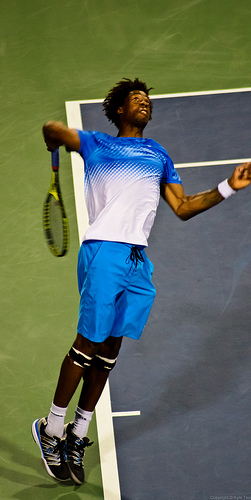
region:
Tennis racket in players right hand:
[38, 117, 67, 254]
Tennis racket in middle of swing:
[41, 123, 64, 249]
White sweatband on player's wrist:
[212, 174, 227, 190]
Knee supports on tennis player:
[62, 341, 109, 362]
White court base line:
[58, 94, 112, 490]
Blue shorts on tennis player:
[69, 236, 148, 327]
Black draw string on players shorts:
[123, 241, 140, 269]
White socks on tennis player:
[44, 401, 92, 434]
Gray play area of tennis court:
[74, 85, 235, 491]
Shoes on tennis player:
[30, 417, 94, 485]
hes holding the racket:
[44, 141, 64, 161]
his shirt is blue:
[94, 143, 114, 155]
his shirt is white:
[118, 193, 133, 205]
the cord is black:
[129, 246, 143, 259]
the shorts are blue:
[89, 257, 105, 272]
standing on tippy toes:
[47, 467, 89, 486]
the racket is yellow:
[48, 183, 60, 200]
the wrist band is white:
[216, 178, 229, 194]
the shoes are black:
[53, 467, 66, 475]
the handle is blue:
[49, 153, 60, 162]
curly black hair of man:
[97, 75, 154, 119]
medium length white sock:
[42, 400, 68, 435]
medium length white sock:
[69, 405, 94, 440]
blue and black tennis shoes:
[32, 419, 69, 482]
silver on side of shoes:
[45, 437, 55, 456]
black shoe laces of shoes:
[45, 435, 91, 449]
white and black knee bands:
[63, 347, 123, 370]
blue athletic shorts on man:
[68, 239, 158, 330]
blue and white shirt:
[53, 133, 170, 244]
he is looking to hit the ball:
[21, 50, 191, 476]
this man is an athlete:
[19, 52, 238, 491]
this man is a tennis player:
[9, 50, 249, 492]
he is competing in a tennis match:
[16, 26, 242, 495]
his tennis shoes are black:
[20, 408, 98, 493]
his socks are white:
[38, 383, 97, 442]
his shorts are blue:
[71, 231, 163, 346]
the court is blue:
[72, 98, 250, 498]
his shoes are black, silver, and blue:
[28, 411, 109, 489]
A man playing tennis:
[27, 76, 250, 490]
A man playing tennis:
[28, 73, 245, 490]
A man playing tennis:
[27, 68, 247, 493]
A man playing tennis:
[23, 73, 242, 489]